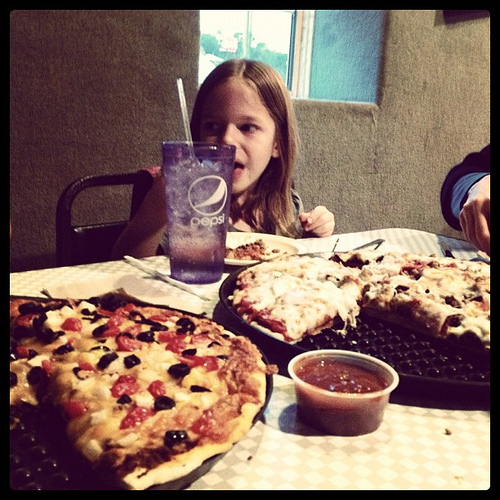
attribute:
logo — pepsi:
[187, 174, 228, 215]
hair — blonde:
[158, 50, 332, 134]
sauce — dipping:
[294, 362, 386, 436]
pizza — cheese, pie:
[239, 251, 491, 336]